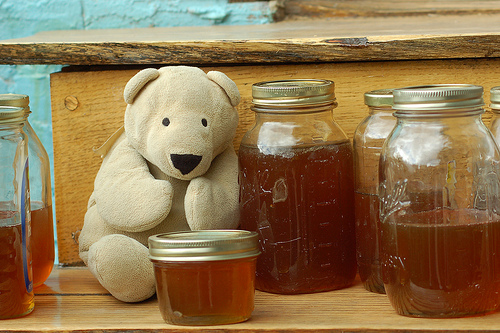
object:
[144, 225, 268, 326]
jar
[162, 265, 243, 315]
honey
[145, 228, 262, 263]
lid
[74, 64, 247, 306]
teddy bear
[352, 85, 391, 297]
jars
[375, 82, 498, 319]
jar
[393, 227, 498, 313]
honey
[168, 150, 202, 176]
nose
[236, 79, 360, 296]
jar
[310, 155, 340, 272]
measurement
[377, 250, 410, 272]
label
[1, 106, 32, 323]
jar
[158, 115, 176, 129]
eyes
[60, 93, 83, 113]
nail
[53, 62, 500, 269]
board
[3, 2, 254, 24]
wall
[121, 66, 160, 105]
ears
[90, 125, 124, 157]
tag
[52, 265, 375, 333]
shelf